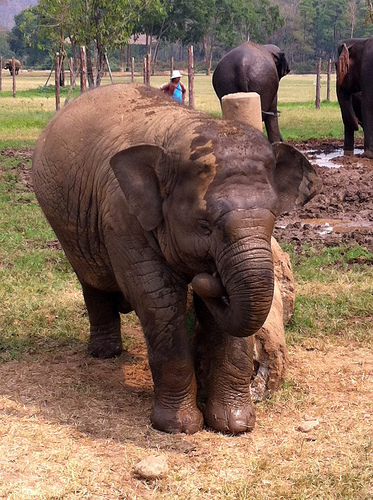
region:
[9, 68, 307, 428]
Small brown elephant standing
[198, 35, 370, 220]
Small brown elephant standing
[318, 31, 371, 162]
Small brown elephant standing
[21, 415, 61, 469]
Small batch of brown grass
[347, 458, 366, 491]
Small batch of brown grass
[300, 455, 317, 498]
Small batch of brown grass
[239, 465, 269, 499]
Small batch of brown grass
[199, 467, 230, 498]
Small batch of brown grass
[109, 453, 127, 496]
Small batch of brown grass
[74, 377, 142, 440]
Small batch of brown grass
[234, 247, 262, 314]
wrinkles on elephants trunk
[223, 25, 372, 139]
elephants standing in mud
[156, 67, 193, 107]
person watching the elephants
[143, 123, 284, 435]
elephant with mud all over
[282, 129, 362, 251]
mud pit on the ground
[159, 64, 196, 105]
person wearing a white hat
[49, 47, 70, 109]
wooden posts used to create fencing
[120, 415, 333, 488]
small rocks on the ground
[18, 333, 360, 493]
patch of dry brown grass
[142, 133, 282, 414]
elephant with it's trunk curled up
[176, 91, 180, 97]
the shirt is light blue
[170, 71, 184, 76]
the cap is white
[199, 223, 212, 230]
the animal has an eye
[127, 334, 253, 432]
the animal has legs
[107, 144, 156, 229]
the animal has ears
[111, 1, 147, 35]
the tree has branches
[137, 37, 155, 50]
the tees has stems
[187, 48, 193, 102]
the log is brown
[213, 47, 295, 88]
the animal is black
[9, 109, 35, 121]
this is the grass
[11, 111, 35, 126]
the grass is green in color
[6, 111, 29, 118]
the grass is short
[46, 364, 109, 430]
this is the ground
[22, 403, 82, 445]
the ground is arid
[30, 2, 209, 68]
these are some trees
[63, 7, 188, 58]
the trees are short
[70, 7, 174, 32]
the leaves are green in color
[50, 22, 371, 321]
these are some elephants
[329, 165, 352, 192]
this is some mud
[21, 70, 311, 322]
a close up of an elephant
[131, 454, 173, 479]
a rock on the ground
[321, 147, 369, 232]
a mud hole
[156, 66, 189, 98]
person observing elephants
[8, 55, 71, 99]
a wire and wood fence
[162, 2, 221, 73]
trees in a field of elephants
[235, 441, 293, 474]
dead grass in a field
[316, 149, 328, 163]
a mud puddle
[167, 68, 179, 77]
man wearing a white bucket hat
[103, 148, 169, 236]
ear of an elephant